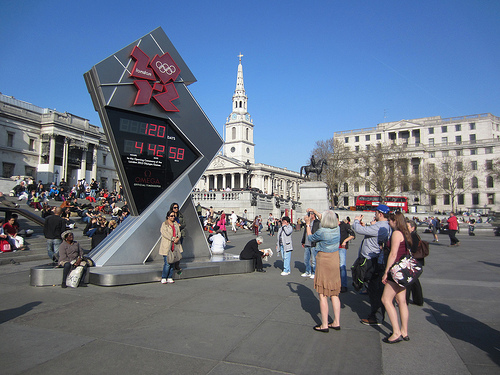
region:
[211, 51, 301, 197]
building with columns and steeple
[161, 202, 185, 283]
people posing for photo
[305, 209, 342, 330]
woman with camera in hand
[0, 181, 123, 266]
people sitting on steps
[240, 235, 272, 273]
seated man in black suit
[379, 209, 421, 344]
woman with bag hanging from shoulder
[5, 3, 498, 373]
Exterior shot, daytime, clothing suggestive of fall, or spring.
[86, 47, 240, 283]
Modern sculpture with digital readout and tourists posing before it.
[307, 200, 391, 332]
People photographing posers before sculpture.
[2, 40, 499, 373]
View of plaza with historical buildings, modern artwork and lots of people.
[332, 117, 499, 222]
Elderly, white, rectangular building, fronted by bare trees.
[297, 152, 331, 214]
Stone pedestal with stature of man on horse.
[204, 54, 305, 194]
Historical building with columns and steep steeple.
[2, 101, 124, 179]
Old building with intricate carving.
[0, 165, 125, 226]
Steps, showing throngs of people.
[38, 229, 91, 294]
Person seated on edge of sculpture.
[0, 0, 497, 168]
A blue sky.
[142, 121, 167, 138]
Red number 120.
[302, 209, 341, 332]
Grey haired woman in a jean jacket.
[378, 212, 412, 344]
Brown haired girl in black flats and maroon shirt.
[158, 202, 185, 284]
Two dark haired people posing for a photo.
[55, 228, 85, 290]
Black woman sitting down on a statue with a grey coat on.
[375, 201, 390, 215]
Bright blue hat on a man's head taking a picture.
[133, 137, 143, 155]
Red number 4 before a 42.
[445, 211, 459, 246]
A large man in a red shirt and black pants.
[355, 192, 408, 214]
Red double decker bus.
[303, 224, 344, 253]
A blue jacket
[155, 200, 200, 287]
Two ladies being photographed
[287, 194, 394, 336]
People taking photos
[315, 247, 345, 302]
A brown dress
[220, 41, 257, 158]
A tower in the background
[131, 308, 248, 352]
Paved surface in the photo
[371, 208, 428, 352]
A woman holding a bag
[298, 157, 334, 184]
A statue of a horse and rider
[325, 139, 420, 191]
Trees growing near the buildings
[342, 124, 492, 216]
Buildings in the background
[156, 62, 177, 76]
the olympic symbol in white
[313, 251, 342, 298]
the medium length brown skirt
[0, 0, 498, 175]
the sky is blue and clear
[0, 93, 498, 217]
the large gray buildings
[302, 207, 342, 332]
woman taking a picture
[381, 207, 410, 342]
woman wearing shorts and tank top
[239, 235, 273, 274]
man reading the newspaper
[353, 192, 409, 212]
double decker bus in the distance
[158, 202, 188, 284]
two women next to digital clock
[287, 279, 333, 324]
woman's shadow on the ground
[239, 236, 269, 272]
man wearing dark suit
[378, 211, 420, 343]
girl carrying a bag